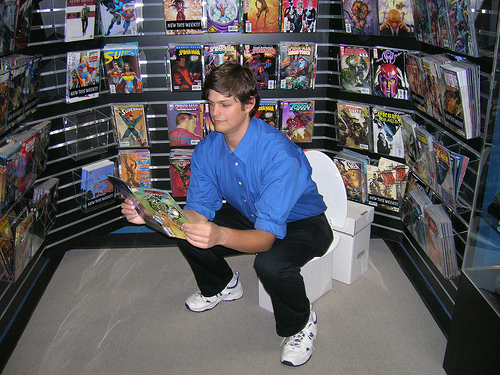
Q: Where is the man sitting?
A: On a toilet.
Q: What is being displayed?
A: Comic books.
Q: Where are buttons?
A: On man's blue shirt.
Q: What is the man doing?
A: Reading a comic.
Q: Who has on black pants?
A: The man.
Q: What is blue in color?
A: Man's shirt.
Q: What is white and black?
A: Man's sneakers.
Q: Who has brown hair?
A: The man.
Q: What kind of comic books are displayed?
A: Superhero comics.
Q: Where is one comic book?
A: In man's hands.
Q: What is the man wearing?
A: Blue shirt.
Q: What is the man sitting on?
A: Small toilet.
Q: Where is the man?
A: On the toilet.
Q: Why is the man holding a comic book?
A: Reading.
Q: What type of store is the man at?
A: Comic book store.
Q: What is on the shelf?
A: Comic books.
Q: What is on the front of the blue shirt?
A: Buttons.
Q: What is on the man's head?
A: Brown hair.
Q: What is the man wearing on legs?
A: Pants.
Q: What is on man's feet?
A: White shoes.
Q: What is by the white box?
A: White toilet.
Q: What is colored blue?
A: The man's shirt.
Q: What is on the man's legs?
A: Black pants.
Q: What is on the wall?
A: Comic books.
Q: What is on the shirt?
A: Buttons.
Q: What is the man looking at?
A: Comics.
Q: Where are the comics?
A: On the wall.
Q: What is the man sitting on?
A: Plastic toilet.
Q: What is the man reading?
A: Comic book.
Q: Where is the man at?
A: Comic book store.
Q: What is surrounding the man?
A: Comic books.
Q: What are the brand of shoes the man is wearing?
A: White New Balance.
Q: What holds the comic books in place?
A: Plastic casing.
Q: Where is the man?
A: Book store.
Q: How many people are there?
A: One.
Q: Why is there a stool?
A: To sit.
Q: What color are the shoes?
A: White.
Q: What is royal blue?
A: A shirt.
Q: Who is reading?
A: The man.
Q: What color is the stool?
A: White.